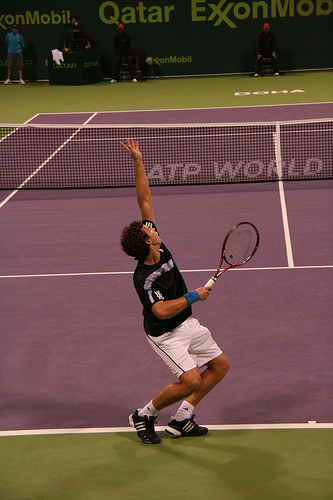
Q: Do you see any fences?
A: No, there are no fences.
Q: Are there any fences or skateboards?
A: No, there are no fences or skateboards.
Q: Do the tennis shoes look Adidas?
A: Yes, the shoes are adidas.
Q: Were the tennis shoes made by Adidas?
A: Yes, the shoes were made by adidas.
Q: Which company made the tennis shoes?
A: Adidas made adidas.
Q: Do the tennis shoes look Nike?
A: No, the shoes are adidas.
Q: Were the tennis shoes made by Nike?
A: No, the shoes were made by adidas.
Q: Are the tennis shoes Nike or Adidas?
A: The shoes are adidas.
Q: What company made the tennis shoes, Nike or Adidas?
A: The shoes were made adidas.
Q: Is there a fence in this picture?
A: No, there are no fences.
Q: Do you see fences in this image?
A: No, there are no fences.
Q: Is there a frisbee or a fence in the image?
A: No, there are no fences or frisbees.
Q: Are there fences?
A: No, there are no fences.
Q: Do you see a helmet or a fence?
A: No, there are no fences or helmets.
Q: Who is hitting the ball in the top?
A: The man is hitting the ball.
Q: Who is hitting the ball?
A: The man is hitting the ball.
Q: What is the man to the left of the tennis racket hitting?
A: The man is hitting the ball.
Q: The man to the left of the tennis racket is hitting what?
A: The man is hitting the ball.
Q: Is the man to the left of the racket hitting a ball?
A: Yes, the man is hitting a ball.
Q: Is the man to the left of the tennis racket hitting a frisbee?
A: No, the man is hitting a ball.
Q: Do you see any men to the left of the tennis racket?
A: Yes, there is a man to the left of the tennis racket.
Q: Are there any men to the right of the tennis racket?
A: No, the man is to the left of the tennis racket.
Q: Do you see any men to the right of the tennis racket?
A: No, the man is to the left of the tennis racket.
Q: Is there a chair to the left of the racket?
A: No, there is a man to the left of the racket.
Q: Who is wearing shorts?
A: The man is wearing shorts.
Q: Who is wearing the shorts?
A: The man is wearing shorts.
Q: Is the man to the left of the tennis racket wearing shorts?
A: Yes, the man is wearing shorts.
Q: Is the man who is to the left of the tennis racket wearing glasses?
A: No, the man is wearing shorts.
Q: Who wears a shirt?
A: The man wears a shirt.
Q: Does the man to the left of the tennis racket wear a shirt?
A: Yes, the man wears a shirt.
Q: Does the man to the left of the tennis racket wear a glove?
A: No, the man wears a shirt.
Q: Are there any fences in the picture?
A: No, there are no fences.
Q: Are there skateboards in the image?
A: No, there are no skateboards.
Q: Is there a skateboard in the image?
A: No, there are no skateboards.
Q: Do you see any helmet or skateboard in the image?
A: No, there are no skateboards or helmets.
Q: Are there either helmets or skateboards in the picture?
A: No, there are no skateboards or helmets.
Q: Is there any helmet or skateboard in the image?
A: No, there are no skateboards or helmets.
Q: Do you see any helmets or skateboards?
A: No, there are no skateboards or helmets.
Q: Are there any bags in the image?
A: No, there are no bags.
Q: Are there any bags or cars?
A: No, there are no bags or cars.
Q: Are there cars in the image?
A: No, there are no cars.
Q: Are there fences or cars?
A: No, there are no cars or fences.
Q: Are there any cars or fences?
A: No, there are no cars or fences.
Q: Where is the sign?
A: The sign is on the floor.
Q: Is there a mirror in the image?
A: No, there are no mirrors.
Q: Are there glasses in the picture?
A: No, there are no glasses.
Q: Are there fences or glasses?
A: No, there are no glasses or fences.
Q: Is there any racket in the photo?
A: Yes, there is a racket.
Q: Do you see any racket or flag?
A: Yes, there is a racket.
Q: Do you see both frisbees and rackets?
A: No, there is a racket but no frisbees.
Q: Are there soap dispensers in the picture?
A: No, there are no soap dispensers.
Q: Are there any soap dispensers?
A: No, there are no soap dispensers.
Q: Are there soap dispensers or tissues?
A: No, there are no soap dispensers or tissues.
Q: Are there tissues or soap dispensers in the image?
A: No, there are no soap dispensers or tissues.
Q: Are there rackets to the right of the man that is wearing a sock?
A: Yes, there is a racket to the right of the man.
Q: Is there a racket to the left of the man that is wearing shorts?
A: No, the racket is to the right of the man.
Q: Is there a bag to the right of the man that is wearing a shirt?
A: No, there is a racket to the right of the man.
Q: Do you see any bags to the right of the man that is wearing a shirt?
A: No, there is a racket to the right of the man.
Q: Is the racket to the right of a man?
A: Yes, the racket is to the right of a man.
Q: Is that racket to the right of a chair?
A: No, the racket is to the right of a man.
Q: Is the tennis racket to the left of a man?
A: No, the tennis racket is to the right of a man.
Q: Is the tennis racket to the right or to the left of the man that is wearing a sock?
A: The tennis racket is to the right of the man.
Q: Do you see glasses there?
A: No, there are no glasses.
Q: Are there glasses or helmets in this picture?
A: No, there are no glasses or helmets.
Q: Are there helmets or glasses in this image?
A: No, there are no glasses or helmets.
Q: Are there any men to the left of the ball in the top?
A: Yes, there is a man to the left of the ball.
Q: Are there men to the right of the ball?
A: No, the man is to the left of the ball.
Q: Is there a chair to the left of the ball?
A: No, there is a man to the left of the ball.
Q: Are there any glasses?
A: No, there are no glasses.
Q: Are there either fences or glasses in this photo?
A: No, there are no glasses or fences.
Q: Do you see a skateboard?
A: No, there are no skateboards.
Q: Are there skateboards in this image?
A: No, there are no skateboards.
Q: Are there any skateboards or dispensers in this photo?
A: No, there are no skateboards or dispensers.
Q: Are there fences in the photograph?
A: No, there are no fences.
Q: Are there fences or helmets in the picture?
A: No, there are no fences or helmets.